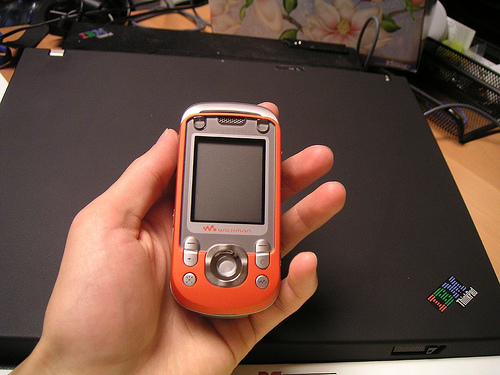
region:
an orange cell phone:
[139, 71, 319, 316]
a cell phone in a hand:
[119, 61, 350, 334]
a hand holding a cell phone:
[119, 99, 362, 374]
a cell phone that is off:
[144, 85, 329, 331]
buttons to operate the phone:
[159, 214, 284, 312]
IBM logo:
[377, 206, 490, 334]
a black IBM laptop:
[4, 18, 497, 370]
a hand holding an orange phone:
[29, 53, 414, 373]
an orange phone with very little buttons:
[34, 56, 444, 371]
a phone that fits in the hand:
[104, 67, 371, 369]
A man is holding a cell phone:
[73, 80, 456, 340]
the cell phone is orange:
[151, 97, 358, 258]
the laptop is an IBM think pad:
[432, 261, 490, 299]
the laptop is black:
[98, 89, 358, 101]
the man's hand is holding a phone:
[97, 79, 368, 271]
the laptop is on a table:
[397, 91, 484, 211]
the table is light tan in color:
[467, 137, 475, 197]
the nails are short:
[116, 150, 415, 244]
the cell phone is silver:
[157, 80, 312, 308]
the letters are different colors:
[429, 237, 482, 292]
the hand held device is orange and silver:
[167, 100, 283, 325]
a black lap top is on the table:
[0, 35, 496, 360]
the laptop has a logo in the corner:
[410, 255, 495, 335]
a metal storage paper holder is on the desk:
[416, 15, 496, 125]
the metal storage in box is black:
[390, 17, 498, 146]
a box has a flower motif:
[210, 1, 421, 71]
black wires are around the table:
[0, 5, 490, 140]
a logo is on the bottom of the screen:
[198, 213, 249, 240]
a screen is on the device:
[195, 137, 262, 227]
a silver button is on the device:
[204, 242, 249, 289]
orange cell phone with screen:
[175, 108, 295, 321]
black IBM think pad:
[13, 39, 488, 336]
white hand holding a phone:
[22, 88, 377, 330]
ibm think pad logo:
[416, 256, 488, 321]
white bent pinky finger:
[281, 248, 331, 325]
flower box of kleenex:
[211, 0, 429, 74]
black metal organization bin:
[380, 21, 491, 146]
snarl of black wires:
[8, 6, 65, 36]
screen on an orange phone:
[191, 134, 271, 228]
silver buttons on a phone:
[174, 236, 286, 310]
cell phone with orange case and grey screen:
[173, 95, 288, 326]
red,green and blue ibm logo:
[422, 261, 482, 321]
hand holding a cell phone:
[54, 101, 369, 372]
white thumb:
[73, 121, 170, 230]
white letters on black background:
[455, 277, 479, 314]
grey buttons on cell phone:
[251, 237, 273, 275]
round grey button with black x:
[182, 267, 203, 292]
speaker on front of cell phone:
[217, 111, 249, 131]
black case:
[337, 83, 442, 230]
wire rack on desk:
[407, 29, 488, 139]